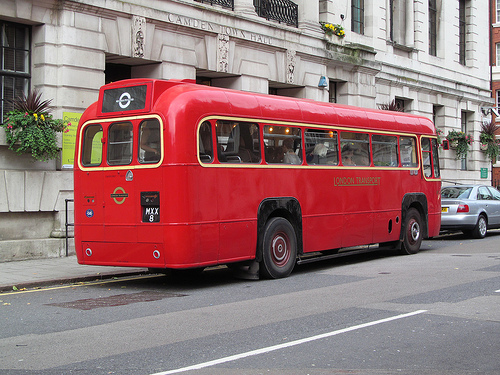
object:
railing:
[255, 0, 298, 25]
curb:
[0, 270, 142, 289]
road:
[3, 228, 499, 372]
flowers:
[6, 96, 67, 160]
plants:
[447, 124, 482, 165]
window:
[0, 18, 35, 126]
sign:
[59, 109, 106, 166]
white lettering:
[140, 201, 162, 223]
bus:
[73, 78, 443, 280]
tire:
[258, 216, 299, 279]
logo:
[110, 186, 129, 205]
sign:
[116, 93, 135, 111]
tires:
[401, 206, 428, 254]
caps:
[407, 217, 423, 241]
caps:
[271, 230, 288, 265]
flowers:
[321, 21, 346, 38]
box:
[321, 22, 347, 38]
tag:
[137, 190, 162, 225]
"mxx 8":
[141, 205, 161, 222]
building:
[1, 0, 495, 260]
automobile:
[441, 180, 500, 240]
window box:
[0, 20, 44, 127]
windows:
[198, 117, 415, 167]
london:
[333, 176, 381, 188]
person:
[138, 121, 161, 158]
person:
[280, 137, 300, 163]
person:
[307, 139, 336, 166]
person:
[345, 149, 356, 167]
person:
[224, 122, 264, 158]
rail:
[63, 199, 85, 257]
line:
[41, 307, 432, 373]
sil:
[0, 121, 66, 217]